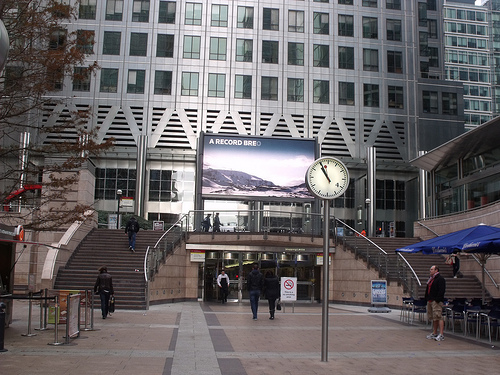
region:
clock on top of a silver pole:
[304, 156, 350, 367]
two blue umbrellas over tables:
[393, 222, 498, 254]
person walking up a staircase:
[121, 214, 142, 257]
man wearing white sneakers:
[421, 330, 446, 341]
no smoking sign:
[280, 275, 297, 303]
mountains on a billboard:
[195, 130, 320, 205]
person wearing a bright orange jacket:
[358, 223, 368, 240]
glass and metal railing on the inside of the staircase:
[132, 206, 425, 303]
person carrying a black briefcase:
[93, 263, 115, 325]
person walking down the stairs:
[443, 251, 462, 281]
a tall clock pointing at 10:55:
[307, 155, 352, 362]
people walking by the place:
[77, 197, 280, 335]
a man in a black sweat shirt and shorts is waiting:
[410, 247, 465, 352]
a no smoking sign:
[270, 270, 305, 320]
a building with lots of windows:
[12, 1, 481, 108]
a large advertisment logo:
[193, 128, 333, 204]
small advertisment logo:
[357, 275, 394, 319]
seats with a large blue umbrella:
[384, 211, 492, 347]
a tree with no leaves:
[7, 13, 89, 306]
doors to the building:
[210, 252, 319, 301]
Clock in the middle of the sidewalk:
[291, 140, 369, 367]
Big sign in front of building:
[179, 120, 318, 224]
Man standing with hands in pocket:
[412, 260, 459, 361]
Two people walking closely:
[243, 253, 284, 324]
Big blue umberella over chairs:
[399, 222, 499, 319]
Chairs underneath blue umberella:
[395, 227, 499, 337]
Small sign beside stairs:
[361, 243, 417, 333]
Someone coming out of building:
[204, 248, 241, 320]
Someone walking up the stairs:
[99, 213, 166, 277]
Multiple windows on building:
[74, 3, 449, 119]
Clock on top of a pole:
[292, 143, 349, 225]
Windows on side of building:
[228, 40, 370, 107]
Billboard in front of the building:
[162, 115, 322, 232]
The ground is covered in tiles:
[150, 307, 274, 371]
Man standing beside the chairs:
[412, 249, 453, 359]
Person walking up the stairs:
[113, 212, 150, 257]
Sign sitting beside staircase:
[352, 260, 412, 330]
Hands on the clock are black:
[312, 160, 330, 195]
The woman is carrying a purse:
[104, 292, 118, 308]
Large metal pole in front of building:
[132, 117, 153, 225]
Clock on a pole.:
[298, 156, 354, 363]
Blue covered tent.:
[396, 216, 499, 341]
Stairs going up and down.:
[53, 199, 497, 313]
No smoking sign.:
[278, 276, 295, 305]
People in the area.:
[88, 201, 466, 346]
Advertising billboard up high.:
[196, 129, 326, 208]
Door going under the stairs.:
[186, 241, 328, 304]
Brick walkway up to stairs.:
[12, 298, 496, 371]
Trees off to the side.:
[2, 99, 107, 323]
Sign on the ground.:
[365, 280, 396, 318]